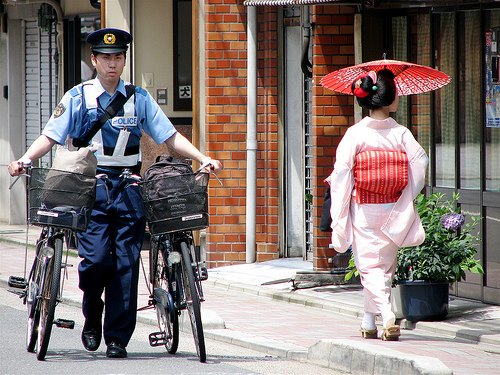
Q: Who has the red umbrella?
A: The woman.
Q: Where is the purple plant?
A: Sidewalk.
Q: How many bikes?
A: Two.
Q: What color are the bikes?
A: Black.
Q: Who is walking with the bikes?
A: Police officer.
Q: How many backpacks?
A: One.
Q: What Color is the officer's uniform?
A: Blue and white.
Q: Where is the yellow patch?
A: Left sleeve of officer.